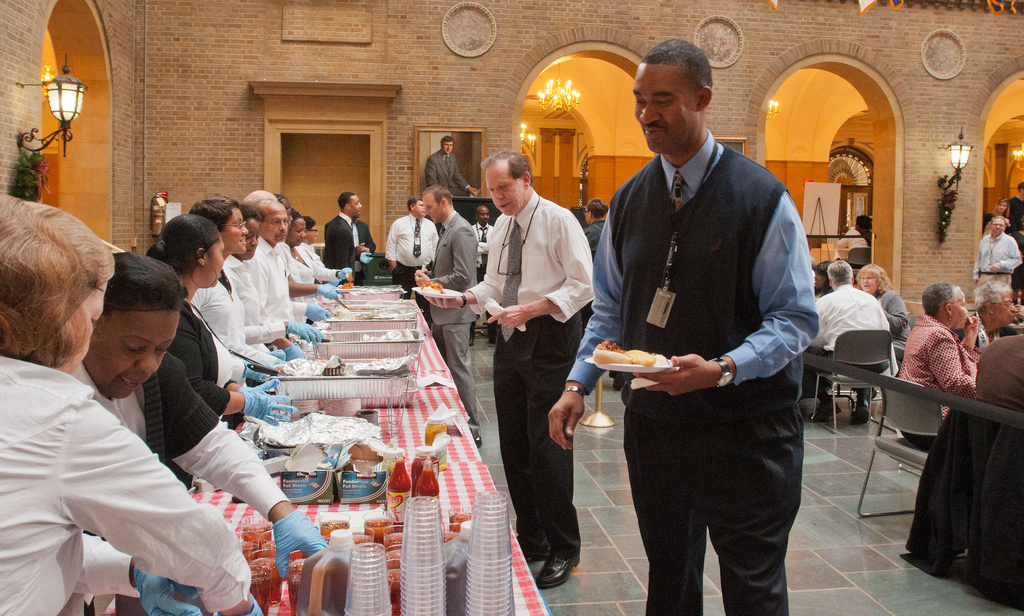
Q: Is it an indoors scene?
A: Yes, it is indoors.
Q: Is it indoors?
A: Yes, it is indoors.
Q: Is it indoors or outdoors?
A: It is indoors.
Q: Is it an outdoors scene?
A: No, it is indoors.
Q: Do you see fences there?
A: No, there are no fences.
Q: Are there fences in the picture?
A: No, there are no fences.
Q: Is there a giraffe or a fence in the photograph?
A: No, there are no fences or giraffes.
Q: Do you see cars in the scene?
A: No, there are no cars.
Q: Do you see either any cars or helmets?
A: No, there are no cars or helmets.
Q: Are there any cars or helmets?
A: No, there are no cars or helmets.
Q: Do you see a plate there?
A: Yes, there is a plate.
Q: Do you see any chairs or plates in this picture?
A: Yes, there is a plate.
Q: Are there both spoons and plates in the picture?
A: No, there is a plate but no spoons.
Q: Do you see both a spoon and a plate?
A: No, there is a plate but no spoons.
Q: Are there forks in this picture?
A: No, there are no forks.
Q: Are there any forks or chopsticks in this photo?
A: No, there are no forks or chopsticks.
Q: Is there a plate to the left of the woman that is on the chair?
A: Yes, there is a plate to the left of the woman.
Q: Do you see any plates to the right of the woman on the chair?
A: No, the plate is to the left of the woman.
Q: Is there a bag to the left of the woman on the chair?
A: No, there is a plate to the left of the woman.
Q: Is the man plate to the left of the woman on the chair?
A: Yes, the plate is to the left of the woman.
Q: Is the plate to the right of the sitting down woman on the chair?
A: No, the plate is to the left of the woman.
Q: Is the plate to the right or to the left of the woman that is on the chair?
A: The plate is to the left of the woman.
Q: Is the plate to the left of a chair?
A: Yes, the plate is to the left of a chair.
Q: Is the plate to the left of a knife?
A: No, the plate is to the left of a chair.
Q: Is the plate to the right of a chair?
A: No, the plate is to the left of a chair.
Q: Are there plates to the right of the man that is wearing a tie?
A: Yes, there is a plate to the right of the man.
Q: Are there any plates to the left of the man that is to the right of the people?
A: No, the plate is to the right of the man.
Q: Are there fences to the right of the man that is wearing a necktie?
A: No, there is a plate to the right of the man.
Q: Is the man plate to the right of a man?
A: Yes, the plate is to the right of a man.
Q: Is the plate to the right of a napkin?
A: No, the plate is to the right of a man.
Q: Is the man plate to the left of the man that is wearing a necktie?
A: No, the plate is to the right of the man.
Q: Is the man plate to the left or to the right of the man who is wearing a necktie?
A: The plate is to the right of the man.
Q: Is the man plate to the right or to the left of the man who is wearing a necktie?
A: The plate is to the right of the man.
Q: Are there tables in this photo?
A: Yes, there is a table.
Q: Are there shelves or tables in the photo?
A: Yes, there is a table.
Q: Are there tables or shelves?
A: Yes, there is a table.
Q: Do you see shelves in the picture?
A: No, there are no shelves.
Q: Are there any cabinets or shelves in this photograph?
A: No, there are no shelves or cabinets.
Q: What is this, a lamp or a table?
A: This is a table.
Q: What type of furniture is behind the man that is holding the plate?
A: The piece of furniture is a table.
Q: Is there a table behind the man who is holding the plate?
A: Yes, there is a table behind the man.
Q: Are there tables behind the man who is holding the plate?
A: Yes, there is a table behind the man.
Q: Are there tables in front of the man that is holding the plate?
A: No, the table is behind the man.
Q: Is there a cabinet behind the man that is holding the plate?
A: No, there is a table behind the man.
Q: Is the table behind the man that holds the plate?
A: Yes, the table is behind the man.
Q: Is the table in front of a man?
A: No, the table is behind a man.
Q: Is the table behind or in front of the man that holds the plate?
A: The table is behind the man.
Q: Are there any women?
A: Yes, there is a woman.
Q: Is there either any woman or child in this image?
A: Yes, there is a woman.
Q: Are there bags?
A: No, there are no bags.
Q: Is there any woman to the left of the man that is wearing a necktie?
A: Yes, there is a woman to the left of the man.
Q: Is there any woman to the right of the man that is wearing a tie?
A: No, the woman is to the left of the man.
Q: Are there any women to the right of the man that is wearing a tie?
A: No, the woman is to the left of the man.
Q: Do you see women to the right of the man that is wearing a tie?
A: No, the woman is to the left of the man.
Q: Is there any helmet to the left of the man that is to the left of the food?
A: No, there is a woman to the left of the man.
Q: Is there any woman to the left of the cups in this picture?
A: Yes, there is a woman to the left of the cups.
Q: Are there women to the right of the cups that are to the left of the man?
A: No, the woman is to the left of the cups.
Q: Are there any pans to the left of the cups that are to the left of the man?
A: No, there is a woman to the left of the cups.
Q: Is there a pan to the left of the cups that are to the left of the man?
A: No, there is a woman to the left of the cups.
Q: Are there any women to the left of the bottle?
A: Yes, there is a woman to the left of the bottle.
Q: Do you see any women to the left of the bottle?
A: Yes, there is a woman to the left of the bottle.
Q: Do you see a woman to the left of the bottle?
A: Yes, there is a woman to the left of the bottle.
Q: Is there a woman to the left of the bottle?
A: Yes, there is a woman to the left of the bottle.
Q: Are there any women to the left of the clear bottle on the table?
A: Yes, there is a woman to the left of the bottle.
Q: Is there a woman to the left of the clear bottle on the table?
A: Yes, there is a woman to the left of the bottle.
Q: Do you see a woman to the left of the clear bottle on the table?
A: Yes, there is a woman to the left of the bottle.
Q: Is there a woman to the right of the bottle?
A: No, the woman is to the left of the bottle.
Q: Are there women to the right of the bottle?
A: No, the woman is to the left of the bottle.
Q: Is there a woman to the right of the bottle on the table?
A: No, the woman is to the left of the bottle.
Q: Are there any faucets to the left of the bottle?
A: No, there is a woman to the left of the bottle.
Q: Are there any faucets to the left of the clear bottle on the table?
A: No, there is a woman to the left of the bottle.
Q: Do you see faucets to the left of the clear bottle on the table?
A: No, there is a woman to the left of the bottle.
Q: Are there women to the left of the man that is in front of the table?
A: Yes, there is a woman to the left of the man.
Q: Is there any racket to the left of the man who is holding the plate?
A: No, there is a woman to the left of the man.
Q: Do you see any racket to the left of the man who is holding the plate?
A: No, there is a woman to the left of the man.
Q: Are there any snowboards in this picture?
A: No, there are no snowboards.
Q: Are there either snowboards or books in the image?
A: No, there are no snowboards or books.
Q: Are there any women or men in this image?
A: Yes, there is a woman.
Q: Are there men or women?
A: Yes, there is a woman.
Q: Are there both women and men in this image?
A: Yes, there are both a woman and a man.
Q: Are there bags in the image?
A: No, there are no bags.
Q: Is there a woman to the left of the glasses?
A: Yes, there is a woman to the left of the glasses.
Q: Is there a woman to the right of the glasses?
A: No, the woman is to the left of the glasses.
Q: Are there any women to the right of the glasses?
A: No, the woman is to the left of the glasses.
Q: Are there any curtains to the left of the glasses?
A: No, there is a woman to the left of the glasses.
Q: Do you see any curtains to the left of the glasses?
A: No, there is a woman to the left of the glasses.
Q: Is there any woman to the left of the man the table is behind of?
A: Yes, there is a woman to the left of the man.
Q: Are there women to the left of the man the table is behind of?
A: Yes, there is a woman to the left of the man.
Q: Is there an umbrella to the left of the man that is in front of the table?
A: No, there is a woman to the left of the man.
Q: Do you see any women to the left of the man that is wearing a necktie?
A: Yes, there is a woman to the left of the man.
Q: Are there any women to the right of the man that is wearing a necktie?
A: No, the woman is to the left of the man.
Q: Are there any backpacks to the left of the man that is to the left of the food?
A: No, there is a woman to the left of the man.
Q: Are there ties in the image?
A: Yes, there is a tie.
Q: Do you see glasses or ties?
A: Yes, there is a tie.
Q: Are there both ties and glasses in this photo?
A: Yes, there are both a tie and glasses.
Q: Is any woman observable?
A: Yes, there is a woman.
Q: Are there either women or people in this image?
A: Yes, there is a woman.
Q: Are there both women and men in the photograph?
A: Yes, there are both a woman and a man.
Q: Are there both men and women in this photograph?
A: Yes, there are both a woman and a man.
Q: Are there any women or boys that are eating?
A: Yes, the woman is eating.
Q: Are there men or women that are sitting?
A: Yes, the woman is sitting.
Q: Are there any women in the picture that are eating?
A: Yes, there is a woman that is eating.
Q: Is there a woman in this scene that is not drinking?
A: Yes, there is a woman that is eating.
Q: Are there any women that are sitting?
A: Yes, there is a woman that is sitting.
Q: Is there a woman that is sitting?
A: Yes, there is a woman that is sitting.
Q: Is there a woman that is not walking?
A: Yes, there is a woman that is sitting.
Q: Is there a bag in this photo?
A: No, there are no bags.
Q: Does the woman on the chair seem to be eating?
A: Yes, the woman is eating.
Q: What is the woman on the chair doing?
A: The woman is eating.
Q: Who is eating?
A: The woman is eating.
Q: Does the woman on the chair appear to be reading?
A: No, the woman is eating.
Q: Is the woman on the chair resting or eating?
A: The woman is eating.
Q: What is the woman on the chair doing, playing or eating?
A: The woman is eating.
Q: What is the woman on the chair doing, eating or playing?
A: The woman is eating.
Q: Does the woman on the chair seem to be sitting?
A: Yes, the woman is sitting.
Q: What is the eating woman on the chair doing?
A: The woman is sitting.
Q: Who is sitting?
A: The woman is sitting.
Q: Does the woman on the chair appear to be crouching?
A: No, the woman is sitting.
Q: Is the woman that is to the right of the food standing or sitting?
A: The woman is sitting.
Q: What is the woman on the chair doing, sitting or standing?
A: The woman is sitting.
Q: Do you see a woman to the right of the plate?
A: Yes, there is a woman to the right of the plate.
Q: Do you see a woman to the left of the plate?
A: No, the woman is to the right of the plate.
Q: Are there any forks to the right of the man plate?
A: No, there is a woman to the right of the plate.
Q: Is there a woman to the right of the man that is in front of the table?
A: Yes, there is a woman to the right of the man.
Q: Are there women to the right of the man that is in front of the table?
A: Yes, there is a woman to the right of the man.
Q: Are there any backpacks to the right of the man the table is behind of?
A: No, there is a woman to the right of the man.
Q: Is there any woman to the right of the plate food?
A: Yes, there is a woman to the right of the food.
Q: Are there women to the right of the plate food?
A: Yes, there is a woman to the right of the food.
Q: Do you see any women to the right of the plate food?
A: Yes, there is a woman to the right of the food.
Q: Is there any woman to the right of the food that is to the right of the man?
A: Yes, there is a woman to the right of the food.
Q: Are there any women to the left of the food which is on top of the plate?
A: No, the woman is to the right of the food.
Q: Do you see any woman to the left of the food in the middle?
A: No, the woman is to the right of the food.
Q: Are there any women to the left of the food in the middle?
A: No, the woman is to the right of the food.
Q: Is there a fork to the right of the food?
A: No, there is a woman to the right of the food.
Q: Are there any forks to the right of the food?
A: No, there is a woman to the right of the food.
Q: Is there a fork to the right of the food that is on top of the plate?
A: No, there is a woman to the right of the food.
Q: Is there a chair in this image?
A: Yes, there is a chair.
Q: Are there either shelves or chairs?
A: Yes, there is a chair.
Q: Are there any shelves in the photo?
A: No, there are no shelves.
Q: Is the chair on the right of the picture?
A: Yes, the chair is on the right of the image.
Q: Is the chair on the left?
A: No, the chair is on the right of the image.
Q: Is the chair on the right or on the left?
A: The chair is on the right of the image.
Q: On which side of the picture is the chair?
A: The chair is on the right of the image.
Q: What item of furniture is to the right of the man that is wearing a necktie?
A: The piece of furniture is a chair.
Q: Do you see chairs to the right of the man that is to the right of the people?
A: Yes, there is a chair to the right of the man.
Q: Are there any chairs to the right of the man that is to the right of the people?
A: Yes, there is a chair to the right of the man.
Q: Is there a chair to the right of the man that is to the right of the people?
A: Yes, there is a chair to the right of the man.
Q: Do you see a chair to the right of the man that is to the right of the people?
A: Yes, there is a chair to the right of the man.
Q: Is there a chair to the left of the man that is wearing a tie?
A: No, the chair is to the right of the man.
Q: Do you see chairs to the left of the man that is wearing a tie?
A: No, the chair is to the right of the man.